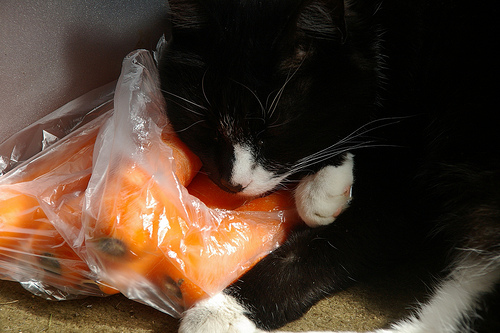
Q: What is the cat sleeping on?
A: Carrots.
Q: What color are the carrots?
A: Orange.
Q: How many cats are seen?
A: One.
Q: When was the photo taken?
A: Nighttime.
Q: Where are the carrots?
A: On the floor.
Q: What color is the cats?
A: Black and white.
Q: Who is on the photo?
A: No one.